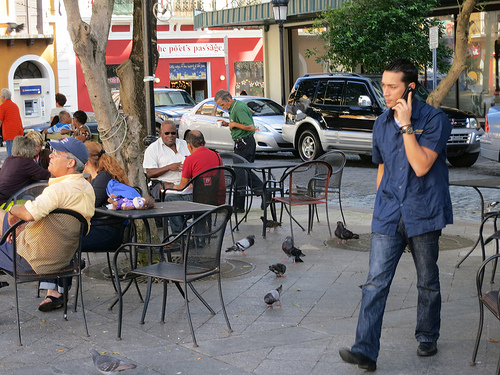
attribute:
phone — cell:
[396, 83, 416, 107]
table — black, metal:
[223, 152, 310, 243]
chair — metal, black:
[258, 153, 338, 253]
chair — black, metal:
[284, 145, 351, 235]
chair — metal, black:
[213, 146, 278, 229]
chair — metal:
[185, 165, 237, 245]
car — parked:
[278, 72, 485, 172]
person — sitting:
[6, 119, 128, 340]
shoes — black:
[326, 322, 442, 369]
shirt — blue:
[372, 100, 452, 233]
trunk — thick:
[97, 120, 164, 282]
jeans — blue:
[357, 223, 444, 338]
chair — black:
[109, 204, 240, 352]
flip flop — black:
[33, 290, 68, 315]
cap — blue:
[47, 135, 89, 165]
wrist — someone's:
[384, 95, 419, 135]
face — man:
[381, 70, 405, 108]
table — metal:
[89, 191, 231, 328]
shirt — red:
[178, 143, 229, 205]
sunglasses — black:
[141, 109, 188, 150]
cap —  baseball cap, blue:
[53, 134, 84, 156]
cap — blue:
[46, 130, 90, 164]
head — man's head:
[45, 148, 85, 174]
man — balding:
[181, 126, 236, 205]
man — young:
[340, 61, 452, 370]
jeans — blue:
[354, 216, 440, 359]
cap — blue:
[46, 128, 89, 156]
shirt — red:
[181, 146, 232, 194]